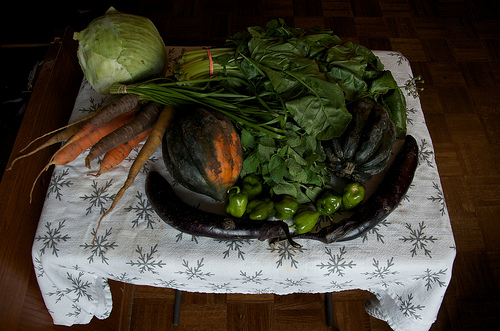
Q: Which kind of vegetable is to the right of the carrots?
A: The vegetable is a squash.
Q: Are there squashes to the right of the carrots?
A: Yes, there is a squash to the right of the carrots.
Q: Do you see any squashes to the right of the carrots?
A: Yes, there is a squash to the right of the carrots.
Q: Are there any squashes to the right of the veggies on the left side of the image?
A: Yes, there is a squash to the right of the carrots.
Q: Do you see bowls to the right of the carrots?
A: No, there is a squash to the right of the carrots.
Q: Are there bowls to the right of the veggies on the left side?
A: No, there is a squash to the right of the carrots.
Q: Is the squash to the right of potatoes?
A: No, the squash is to the right of the carrots.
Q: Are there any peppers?
A: Yes, there are peppers.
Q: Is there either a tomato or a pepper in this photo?
A: Yes, there are peppers.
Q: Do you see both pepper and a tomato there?
A: No, there are peppers but no tomatoes.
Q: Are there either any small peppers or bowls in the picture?
A: Yes, there are small peppers.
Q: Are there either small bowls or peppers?
A: Yes, there are small peppers.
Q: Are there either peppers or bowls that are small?
A: Yes, the peppers are small.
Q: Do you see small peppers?
A: Yes, there are small peppers.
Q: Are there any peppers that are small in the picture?
A: Yes, there are small peppers.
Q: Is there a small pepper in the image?
A: Yes, there are small peppers.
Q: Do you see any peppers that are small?
A: Yes, there are peppers that are small.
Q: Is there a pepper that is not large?
A: Yes, there are small peppers.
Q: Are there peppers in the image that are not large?
A: Yes, there are small peppers.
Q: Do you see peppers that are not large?
A: Yes, there are small peppers.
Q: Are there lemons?
A: No, there are no lemons.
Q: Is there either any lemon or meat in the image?
A: No, there are no lemons or meat.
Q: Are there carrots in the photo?
A: Yes, there are carrots.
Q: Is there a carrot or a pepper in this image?
A: Yes, there are carrots.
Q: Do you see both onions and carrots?
A: Yes, there are both carrots and an onion.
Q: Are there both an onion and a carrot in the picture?
A: Yes, there are both a carrot and an onion.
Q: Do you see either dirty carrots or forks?
A: Yes, there are dirty carrots.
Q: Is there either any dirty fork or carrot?
A: Yes, there are dirty carrots.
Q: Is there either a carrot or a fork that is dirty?
A: Yes, the carrots are dirty.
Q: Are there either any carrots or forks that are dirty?
A: Yes, the carrots are dirty.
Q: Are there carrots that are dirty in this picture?
A: Yes, there are dirty carrots.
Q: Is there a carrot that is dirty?
A: Yes, there are carrots that are dirty.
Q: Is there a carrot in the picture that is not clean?
A: Yes, there are dirty carrots.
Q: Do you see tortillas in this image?
A: No, there are no tortillas.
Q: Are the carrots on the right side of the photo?
A: No, the carrots are on the left of the image.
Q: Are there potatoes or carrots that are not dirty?
A: No, there are carrots but they are dirty.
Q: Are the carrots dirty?
A: Yes, the carrots are dirty.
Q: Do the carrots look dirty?
A: Yes, the carrots are dirty.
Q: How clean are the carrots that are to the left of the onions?
A: The carrots are dirty.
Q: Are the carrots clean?
A: No, the carrots are dirty.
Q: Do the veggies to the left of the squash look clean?
A: No, the carrots are dirty.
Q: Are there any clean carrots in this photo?
A: No, there are carrots but they are dirty.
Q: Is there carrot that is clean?
A: No, there are carrots but they are dirty.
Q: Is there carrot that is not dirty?
A: No, there are carrots but they are dirty.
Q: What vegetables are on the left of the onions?
A: The vegetables are carrots.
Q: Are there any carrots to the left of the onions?
A: Yes, there are carrots to the left of the onions.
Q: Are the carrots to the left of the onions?
A: Yes, the carrots are to the left of the onions.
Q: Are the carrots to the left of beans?
A: No, the carrots are to the left of the onions.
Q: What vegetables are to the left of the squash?
A: The vegetables are carrots.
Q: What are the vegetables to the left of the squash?
A: The vegetables are carrots.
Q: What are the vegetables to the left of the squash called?
A: The vegetables are carrots.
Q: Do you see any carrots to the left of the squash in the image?
A: Yes, there are carrots to the left of the squash.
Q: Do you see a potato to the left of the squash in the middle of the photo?
A: No, there are carrots to the left of the squash.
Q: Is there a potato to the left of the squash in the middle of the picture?
A: No, there are carrots to the left of the squash.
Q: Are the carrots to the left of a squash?
A: Yes, the carrots are to the left of a squash.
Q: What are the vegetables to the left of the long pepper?
A: The vegetables are carrots.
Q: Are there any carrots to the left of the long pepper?
A: Yes, there are carrots to the left of the pepper.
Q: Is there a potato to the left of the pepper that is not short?
A: No, there are carrots to the left of the pepper.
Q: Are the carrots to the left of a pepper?
A: Yes, the carrots are to the left of a pepper.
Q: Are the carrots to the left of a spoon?
A: No, the carrots are to the left of a pepper.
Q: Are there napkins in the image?
A: No, there are no napkins.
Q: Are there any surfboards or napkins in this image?
A: No, there are no napkins or surfboards.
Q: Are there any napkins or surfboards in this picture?
A: No, there are no napkins or surfboards.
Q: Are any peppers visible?
A: Yes, there is a pepper.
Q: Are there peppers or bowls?
A: Yes, there is a pepper.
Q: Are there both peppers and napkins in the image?
A: No, there is a pepper but no napkins.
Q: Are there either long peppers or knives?
A: Yes, there is a long pepper.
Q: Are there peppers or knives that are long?
A: Yes, the pepper is long.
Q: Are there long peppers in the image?
A: Yes, there is a long pepper.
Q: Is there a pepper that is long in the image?
A: Yes, there is a long pepper.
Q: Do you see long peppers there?
A: Yes, there is a long pepper.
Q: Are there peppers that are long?
A: Yes, there is a pepper that is long.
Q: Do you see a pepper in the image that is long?
A: Yes, there is a pepper that is long.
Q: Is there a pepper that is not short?
A: Yes, there is a long pepper.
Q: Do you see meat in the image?
A: No, there is no meat.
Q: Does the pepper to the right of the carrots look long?
A: Yes, the pepper is long.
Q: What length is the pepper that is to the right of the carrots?
A: The pepper is long.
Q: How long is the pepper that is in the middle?
A: The pepper is long.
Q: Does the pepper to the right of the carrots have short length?
A: No, the pepper is long.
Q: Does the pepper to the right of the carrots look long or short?
A: The pepper is long.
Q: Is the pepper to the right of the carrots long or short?
A: The pepper is long.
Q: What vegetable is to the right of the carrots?
A: The vegetable is a pepper.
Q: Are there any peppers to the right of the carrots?
A: Yes, there is a pepper to the right of the carrots.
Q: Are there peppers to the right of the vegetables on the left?
A: Yes, there is a pepper to the right of the carrots.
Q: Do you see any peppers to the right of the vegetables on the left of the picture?
A: Yes, there is a pepper to the right of the carrots.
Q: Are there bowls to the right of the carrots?
A: No, there is a pepper to the right of the carrots.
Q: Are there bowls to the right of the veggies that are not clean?
A: No, there is a pepper to the right of the carrots.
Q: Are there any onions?
A: Yes, there are onions.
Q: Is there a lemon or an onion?
A: Yes, there are onions.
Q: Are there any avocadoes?
A: No, there are no avocadoes.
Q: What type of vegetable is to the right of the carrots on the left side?
A: The vegetables are onions.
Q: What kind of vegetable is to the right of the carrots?
A: The vegetables are onions.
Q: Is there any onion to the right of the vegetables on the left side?
A: Yes, there are onions to the right of the carrots.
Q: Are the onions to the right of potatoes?
A: No, the onions are to the right of the carrots.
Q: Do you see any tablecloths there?
A: Yes, there is a tablecloth.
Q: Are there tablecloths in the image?
A: Yes, there is a tablecloth.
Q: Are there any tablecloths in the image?
A: Yes, there is a tablecloth.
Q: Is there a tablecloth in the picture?
A: Yes, there is a tablecloth.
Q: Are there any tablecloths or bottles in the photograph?
A: Yes, there is a tablecloth.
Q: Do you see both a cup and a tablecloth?
A: No, there is a tablecloth but no cups.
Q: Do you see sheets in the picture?
A: No, there are no sheets.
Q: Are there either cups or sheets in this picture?
A: No, there are no sheets or cups.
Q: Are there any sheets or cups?
A: No, there are no sheets or cups.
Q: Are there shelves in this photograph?
A: No, there are no shelves.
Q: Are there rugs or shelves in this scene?
A: No, there are no shelves or rugs.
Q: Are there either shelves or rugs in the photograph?
A: No, there are no shelves or rugs.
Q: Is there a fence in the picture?
A: No, there are no fences.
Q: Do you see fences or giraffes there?
A: No, there are no fences or giraffes.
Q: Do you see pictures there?
A: No, there are no pictures.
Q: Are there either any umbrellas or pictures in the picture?
A: No, there are no pictures or umbrellas.